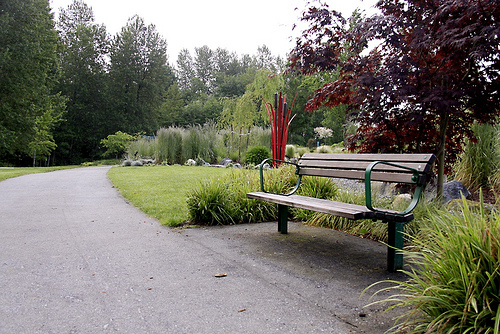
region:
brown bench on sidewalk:
[217, 140, 471, 260]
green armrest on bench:
[367, 154, 432, 259]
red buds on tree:
[288, 35, 486, 182]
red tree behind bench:
[291, 3, 495, 213]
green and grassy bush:
[397, 201, 497, 331]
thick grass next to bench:
[187, 178, 339, 220]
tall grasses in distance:
[122, 133, 282, 165]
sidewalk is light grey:
[17, 171, 119, 329]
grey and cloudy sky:
[157, 11, 278, 68]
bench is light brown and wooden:
[260, 130, 421, 248]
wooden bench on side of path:
[247, 144, 437, 272]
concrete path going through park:
[0, 165, 423, 332]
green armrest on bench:
[256, 157, 304, 197]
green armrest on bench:
[363, 158, 425, 216]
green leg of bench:
[273, 202, 290, 236]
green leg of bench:
[386, 220, 403, 275]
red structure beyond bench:
[258, 89, 301, 166]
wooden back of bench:
[298, 151, 435, 183]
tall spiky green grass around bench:
[183, 162, 498, 332]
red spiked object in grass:
[254, 90, 299, 165]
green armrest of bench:
[257, 155, 302, 196]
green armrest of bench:
[363, 158, 424, 220]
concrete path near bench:
[1, 160, 422, 332]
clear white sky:
[48, 0, 420, 91]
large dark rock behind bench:
[429, 178, 471, 203]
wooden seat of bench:
[244, 189, 395, 221]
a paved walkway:
[1, 163, 376, 332]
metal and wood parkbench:
[246, 150, 436, 274]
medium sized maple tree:
[286, 0, 497, 193]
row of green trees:
[0, 0, 499, 187]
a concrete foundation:
[170, 215, 470, 332]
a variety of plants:
[122, 115, 491, 167]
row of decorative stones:
[121, 152, 499, 232]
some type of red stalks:
[264, 90, 301, 167]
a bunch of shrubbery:
[183, 168, 498, 332]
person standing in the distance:
[311, 129, 322, 148]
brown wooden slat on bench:
[299, 152, 434, 164]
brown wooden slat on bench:
[298, 158, 428, 170]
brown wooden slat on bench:
[293, 165, 421, 185]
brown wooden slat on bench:
[248, 190, 359, 220]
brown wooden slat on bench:
[314, 200, 368, 217]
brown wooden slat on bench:
[371, 208, 386, 215]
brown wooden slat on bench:
[283, 193, 410, 226]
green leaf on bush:
[358, 272, 417, 299]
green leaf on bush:
[361, 297, 409, 314]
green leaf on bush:
[476, 185, 486, 220]